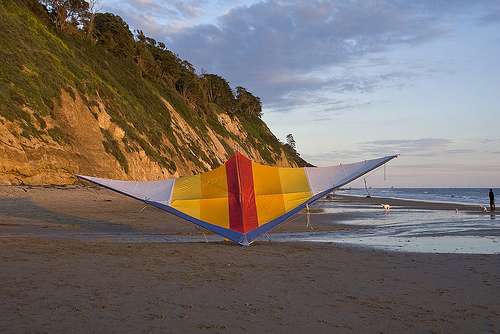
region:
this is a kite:
[78, 146, 409, 263]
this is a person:
[485, 181, 497, 218]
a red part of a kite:
[225, 146, 260, 231]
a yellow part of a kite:
[255, 155, 285, 220]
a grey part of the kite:
[85, 170, 175, 210]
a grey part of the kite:
[300, 145, 398, 195]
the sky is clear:
[120, 0, 488, 201]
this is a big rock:
[10, 0, 315, 195]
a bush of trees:
[97, 5, 140, 60]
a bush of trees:
[173, 48, 273, 133]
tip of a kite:
[327, 187, 339, 194]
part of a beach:
[349, 238, 364, 260]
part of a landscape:
[93, 149, 110, 174]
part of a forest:
[160, 72, 190, 115]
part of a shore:
[384, 253, 389, 280]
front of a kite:
[243, 205, 250, 229]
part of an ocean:
[412, 173, 427, 218]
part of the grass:
[26, 82, 41, 109]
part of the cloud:
[279, 10, 298, 22]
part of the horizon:
[401, 183, 410, 203]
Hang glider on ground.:
[61, 108, 395, 255]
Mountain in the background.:
[69, 11, 211, 191]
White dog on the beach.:
[375, 195, 406, 224]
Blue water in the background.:
[409, 183, 469, 210]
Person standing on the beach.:
[480, 181, 498, 218]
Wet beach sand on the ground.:
[294, 222, 364, 297]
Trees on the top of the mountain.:
[83, 4, 213, 107]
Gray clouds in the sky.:
[242, 15, 319, 86]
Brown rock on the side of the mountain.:
[16, 84, 113, 186]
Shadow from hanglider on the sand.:
[2, 170, 140, 243]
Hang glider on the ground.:
[58, 138, 406, 245]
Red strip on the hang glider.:
[225, 145, 255, 235]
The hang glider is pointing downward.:
[80, 157, 408, 253]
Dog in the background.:
[367, 190, 399, 225]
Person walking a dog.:
[478, 182, 498, 227]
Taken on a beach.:
[9, 5, 494, 332]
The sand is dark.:
[56, 246, 473, 324]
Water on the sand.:
[376, 202, 496, 251]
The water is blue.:
[419, 187, 498, 200]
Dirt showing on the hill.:
[0, 95, 235, 175]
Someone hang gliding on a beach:
[48, 90, 423, 330]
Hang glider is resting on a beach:
[50, 92, 433, 307]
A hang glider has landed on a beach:
[68, 65, 404, 310]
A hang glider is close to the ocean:
[55, 77, 471, 312]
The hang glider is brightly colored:
[70, 106, 406, 292]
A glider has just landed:
[70, 87, 405, 312]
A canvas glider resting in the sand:
[70, 81, 401, 282]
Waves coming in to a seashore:
[395, 180, 450, 211]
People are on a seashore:
[468, 170, 498, 220]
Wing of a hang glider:
[320, 153, 400, 177]